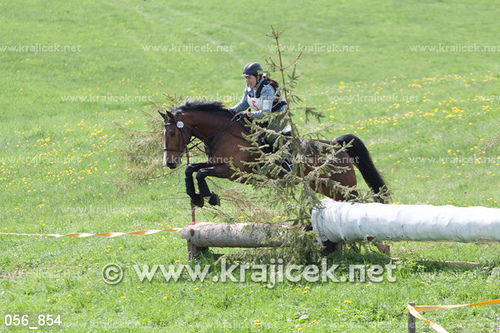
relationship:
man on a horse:
[231, 62, 294, 176] [153, 94, 390, 261]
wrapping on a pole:
[308, 195, 498, 250] [181, 197, 499, 259]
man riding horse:
[224, 60, 326, 206] [159, 94, 397, 232]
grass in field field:
[62, 42, 69, 51] [0, 0, 499, 332]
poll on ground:
[178, 208, 318, 258] [11, 12, 477, 318]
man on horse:
[231, 62, 294, 176] [154, 87, 378, 236]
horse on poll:
[154, 87, 378, 236] [178, 208, 318, 258]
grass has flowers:
[0, 27, 499, 332] [46, 122, 115, 207]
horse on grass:
[157, 97, 398, 254] [0, 27, 499, 332]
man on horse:
[231, 62, 294, 176] [157, 97, 398, 254]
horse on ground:
[157, 97, 398, 254] [11, 12, 477, 318]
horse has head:
[157, 97, 398, 254] [158, 107, 190, 167]